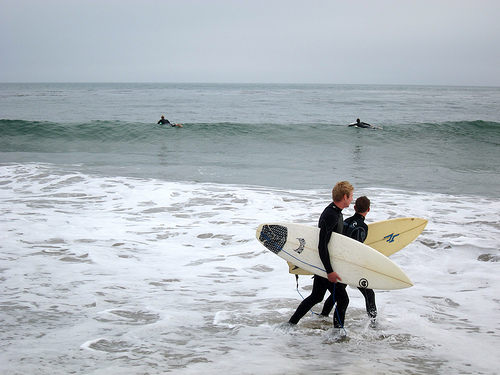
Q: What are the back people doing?
A: Surfing.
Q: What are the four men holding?
A: Surfboards.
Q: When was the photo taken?
A: Daytime.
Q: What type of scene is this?
A: Outdoor.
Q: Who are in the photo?
A: People.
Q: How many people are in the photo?
A: Four.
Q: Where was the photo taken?
A: Waterbody.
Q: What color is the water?
A: Deep green.